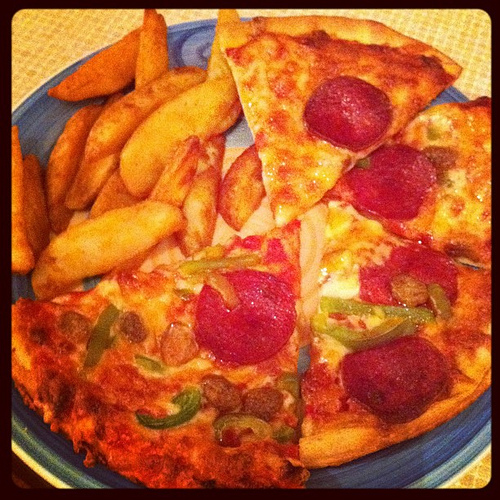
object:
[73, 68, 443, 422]
food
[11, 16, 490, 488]
plate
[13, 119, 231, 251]
fries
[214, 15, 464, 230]
pizza